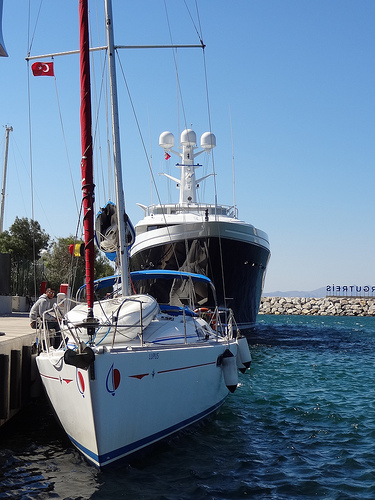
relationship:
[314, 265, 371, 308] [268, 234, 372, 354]
sign in background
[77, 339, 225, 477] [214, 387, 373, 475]
boat on water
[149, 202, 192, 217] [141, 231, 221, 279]
window on boat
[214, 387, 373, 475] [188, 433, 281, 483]
water with waves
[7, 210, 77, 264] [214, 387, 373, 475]
trees by water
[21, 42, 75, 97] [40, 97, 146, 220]
flag on mast